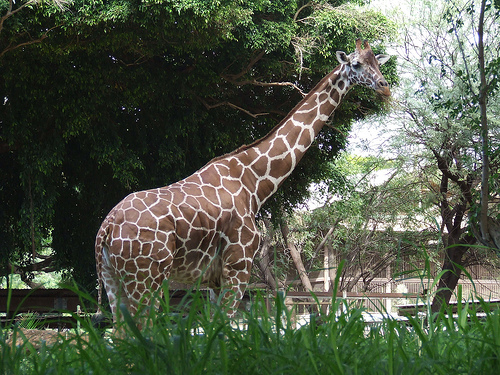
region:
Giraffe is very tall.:
[81, 30, 401, 372]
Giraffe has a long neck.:
[229, 19, 419, 238]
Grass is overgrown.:
[2, 262, 496, 373]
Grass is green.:
[1, 275, 499, 372]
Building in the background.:
[218, 201, 494, 337]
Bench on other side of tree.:
[382, 296, 499, 343]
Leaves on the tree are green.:
[3, 2, 395, 313]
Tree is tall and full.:
[3, 1, 398, 332]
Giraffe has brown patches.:
[55, 30, 406, 353]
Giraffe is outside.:
[3, 1, 499, 315]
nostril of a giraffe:
[374, 74, 392, 96]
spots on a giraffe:
[167, 190, 229, 227]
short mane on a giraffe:
[287, 97, 309, 112]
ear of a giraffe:
[333, 49, 348, 63]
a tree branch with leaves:
[211, 37, 278, 87]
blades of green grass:
[316, 300, 366, 356]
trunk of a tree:
[431, 271, 457, 301]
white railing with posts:
[464, 280, 499, 299]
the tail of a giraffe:
[88, 223, 115, 309]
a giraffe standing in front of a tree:
[53, 35, 446, 345]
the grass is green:
[116, 310, 294, 370]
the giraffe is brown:
[181, 104, 298, 196]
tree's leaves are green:
[59, 31, 169, 131]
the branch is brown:
[442, 223, 474, 318]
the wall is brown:
[379, 258, 426, 304]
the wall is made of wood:
[379, 260, 425, 286]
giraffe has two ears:
[322, 41, 407, 71]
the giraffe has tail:
[70, 211, 133, 306]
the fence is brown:
[290, 290, 370, 300]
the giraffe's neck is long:
[250, 19, 410, 222]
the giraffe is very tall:
[96, 63, 393, 307]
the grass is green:
[55, 306, 486, 363]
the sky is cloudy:
[388, 15, 443, 60]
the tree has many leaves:
[25, 14, 287, 124]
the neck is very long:
[243, 65, 324, 192]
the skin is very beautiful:
[128, 199, 257, 248]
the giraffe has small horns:
[352, 35, 369, 46]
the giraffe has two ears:
[333, 48, 393, 96]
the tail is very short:
[83, 245, 124, 335]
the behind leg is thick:
[118, 264, 165, 332]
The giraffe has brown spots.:
[138, 188, 265, 262]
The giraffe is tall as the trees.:
[111, 28, 399, 318]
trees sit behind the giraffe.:
[33, 10, 407, 166]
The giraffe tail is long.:
[84, 239, 129, 331]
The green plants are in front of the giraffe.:
[30, 302, 496, 365]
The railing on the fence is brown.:
[295, 282, 439, 303]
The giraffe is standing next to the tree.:
[90, 52, 482, 304]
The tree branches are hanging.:
[203, 24, 326, 116]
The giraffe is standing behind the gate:
[80, 53, 432, 333]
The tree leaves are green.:
[406, 30, 493, 322]